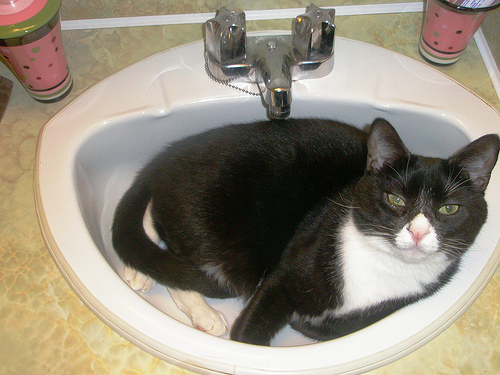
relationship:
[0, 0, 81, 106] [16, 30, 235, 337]
cup on counter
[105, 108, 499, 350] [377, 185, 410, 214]
cat with eye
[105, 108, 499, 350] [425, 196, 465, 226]
cat with eye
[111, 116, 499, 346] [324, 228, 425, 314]
cat on chest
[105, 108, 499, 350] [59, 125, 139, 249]
cat in sink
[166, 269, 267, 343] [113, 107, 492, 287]
paws of cat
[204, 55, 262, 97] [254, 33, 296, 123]
chain on faucet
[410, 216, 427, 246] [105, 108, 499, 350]
nose of cat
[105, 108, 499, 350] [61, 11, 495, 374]
cat laying in sink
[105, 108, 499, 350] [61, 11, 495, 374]
cat on sink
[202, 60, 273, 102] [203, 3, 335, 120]
chain on faucet